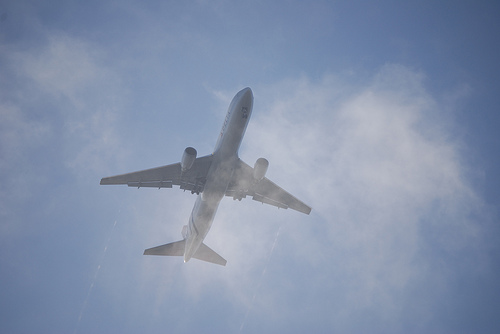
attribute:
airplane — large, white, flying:
[100, 85, 314, 273]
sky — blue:
[204, 48, 234, 70]